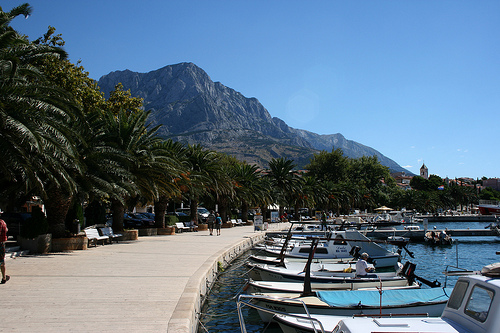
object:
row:
[239, 219, 499, 332]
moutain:
[94, 61, 420, 180]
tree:
[261, 157, 306, 223]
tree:
[145, 137, 195, 228]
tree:
[177, 144, 223, 225]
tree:
[0, 3, 87, 211]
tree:
[43, 109, 142, 238]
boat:
[234, 262, 500, 332]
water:
[198, 220, 500, 332]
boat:
[250, 287, 453, 327]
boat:
[257, 232, 403, 259]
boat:
[250, 259, 439, 292]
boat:
[250, 260, 418, 278]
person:
[215, 213, 222, 236]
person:
[206, 210, 216, 235]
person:
[320, 210, 329, 232]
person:
[0, 208, 10, 284]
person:
[356, 251, 377, 278]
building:
[394, 171, 415, 189]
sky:
[0, 0, 499, 181]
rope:
[194, 316, 210, 333]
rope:
[198, 298, 254, 317]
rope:
[200, 279, 248, 304]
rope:
[224, 255, 250, 266]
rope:
[228, 246, 267, 259]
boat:
[246, 249, 403, 271]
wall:
[187, 222, 302, 333]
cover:
[315, 287, 455, 308]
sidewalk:
[0, 214, 483, 332]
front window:
[463, 283, 495, 323]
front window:
[446, 278, 468, 308]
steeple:
[420, 160, 428, 179]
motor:
[397, 261, 441, 289]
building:
[482, 178, 500, 188]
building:
[447, 179, 468, 186]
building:
[474, 183, 487, 190]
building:
[290, 169, 310, 176]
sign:
[254, 215, 263, 226]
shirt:
[355, 260, 369, 277]